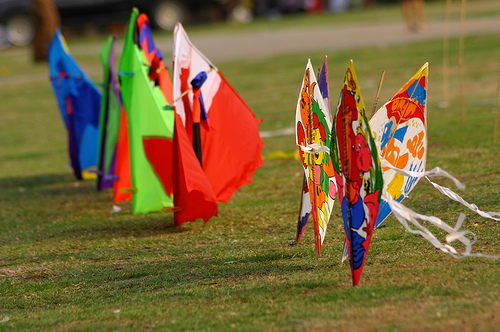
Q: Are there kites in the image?
A: Yes, there is a kite.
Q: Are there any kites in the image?
A: Yes, there is a kite.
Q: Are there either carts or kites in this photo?
A: Yes, there is a kite.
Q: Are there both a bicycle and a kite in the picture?
A: No, there is a kite but no bicycles.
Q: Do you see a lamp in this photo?
A: No, there are no lamps.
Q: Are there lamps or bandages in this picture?
A: No, there are no lamps or bandages.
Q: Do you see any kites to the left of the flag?
A: Yes, there is a kite to the left of the flag.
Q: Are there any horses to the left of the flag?
A: No, there is a kite to the left of the flag.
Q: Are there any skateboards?
A: No, there are no skateboards.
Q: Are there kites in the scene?
A: Yes, there is a kite.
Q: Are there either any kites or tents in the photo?
A: Yes, there is a kite.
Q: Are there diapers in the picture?
A: No, there are no diapers.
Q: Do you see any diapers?
A: No, there are no diapers.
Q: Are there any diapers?
A: No, there are no diapers.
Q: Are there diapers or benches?
A: No, there are no diapers or benches.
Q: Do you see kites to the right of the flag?
A: Yes, there is a kite to the right of the flag.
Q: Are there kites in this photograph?
A: Yes, there is a kite.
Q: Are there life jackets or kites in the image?
A: Yes, there is a kite.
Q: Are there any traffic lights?
A: No, there are no traffic lights.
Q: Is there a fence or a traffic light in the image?
A: No, there are no traffic lights or fences.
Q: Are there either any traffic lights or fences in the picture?
A: No, there are no traffic lights or fences.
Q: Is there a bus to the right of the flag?
A: No, there is a kite to the right of the flag.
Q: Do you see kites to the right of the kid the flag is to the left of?
A: Yes, there is a kite to the right of the child.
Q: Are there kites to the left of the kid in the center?
A: No, the kite is to the right of the child.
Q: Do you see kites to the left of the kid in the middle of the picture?
A: No, the kite is to the right of the child.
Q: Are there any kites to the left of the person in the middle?
A: No, the kite is to the right of the child.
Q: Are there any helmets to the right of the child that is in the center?
A: No, there is a kite to the right of the kid.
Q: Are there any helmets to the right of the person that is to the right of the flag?
A: No, there is a kite to the right of the kid.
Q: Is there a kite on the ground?
A: Yes, there is a kite on the ground.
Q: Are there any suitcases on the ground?
A: No, there is a kite on the ground.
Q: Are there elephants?
A: No, there are no elephants.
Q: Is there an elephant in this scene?
A: No, there are no elephants.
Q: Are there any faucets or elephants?
A: No, there are no elephants or faucets.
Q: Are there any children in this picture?
A: Yes, there is a child.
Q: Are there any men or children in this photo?
A: Yes, there is a child.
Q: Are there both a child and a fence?
A: No, there is a child but no fences.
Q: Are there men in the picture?
A: No, there are no men.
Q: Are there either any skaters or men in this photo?
A: No, there are no men or skaters.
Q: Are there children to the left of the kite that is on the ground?
A: Yes, there is a child to the left of the kite.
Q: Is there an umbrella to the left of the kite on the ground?
A: No, there is a child to the left of the kite.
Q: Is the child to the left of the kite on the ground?
A: Yes, the child is to the left of the kite.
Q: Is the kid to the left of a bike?
A: No, the kid is to the left of the kite.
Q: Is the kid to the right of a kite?
A: No, the kid is to the left of a kite.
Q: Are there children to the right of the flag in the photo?
A: Yes, there is a child to the right of the flag.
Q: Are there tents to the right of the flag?
A: No, there is a child to the right of the flag.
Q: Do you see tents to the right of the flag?
A: No, there is a child to the right of the flag.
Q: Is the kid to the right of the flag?
A: Yes, the kid is to the right of the flag.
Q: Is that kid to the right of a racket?
A: No, the kid is to the right of the flag.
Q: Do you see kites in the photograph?
A: Yes, there is a kite.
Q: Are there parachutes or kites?
A: Yes, there is a kite.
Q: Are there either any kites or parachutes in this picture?
A: Yes, there is a kite.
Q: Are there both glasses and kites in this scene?
A: No, there is a kite but no glasses.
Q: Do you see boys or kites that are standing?
A: Yes, the kite is standing.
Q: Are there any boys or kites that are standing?
A: Yes, the kite is standing.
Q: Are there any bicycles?
A: No, there are no bicycles.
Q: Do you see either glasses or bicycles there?
A: No, there are no bicycles or glasses.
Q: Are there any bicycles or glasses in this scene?
A: No, there are no bicycles or glasses.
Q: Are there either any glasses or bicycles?
A: No, there are no bicycles or glasses.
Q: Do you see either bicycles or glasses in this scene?
A: No, there are no bicycles or glasses.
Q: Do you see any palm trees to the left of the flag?
A: No, there is a kite to the left of the flag.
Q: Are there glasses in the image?
A: No, there are no glasses.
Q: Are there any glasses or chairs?
A: No, there are no glasses or chairs.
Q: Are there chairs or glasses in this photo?
A: No, there are no glasses or chairs.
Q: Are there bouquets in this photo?
A: No, there are no bouquets.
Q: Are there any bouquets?
A: No, there are no bouquets.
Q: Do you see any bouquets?
A: No, there are no bouquets.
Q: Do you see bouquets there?
A: No, there are no bouquets.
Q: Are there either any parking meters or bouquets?
A: No, there are no bouquets or parking meters.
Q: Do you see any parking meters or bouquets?
A: No, there are no bouquets or parking meters.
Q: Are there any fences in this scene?
A: No, there are no fences.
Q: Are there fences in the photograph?
A: No, there are no fences.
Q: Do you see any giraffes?
A: No, there are no giraffes.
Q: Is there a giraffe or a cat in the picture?
A: No, there are no giraffes or cats.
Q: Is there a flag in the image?
A: Yes, there is a flag.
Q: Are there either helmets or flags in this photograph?
A: Yes, there is a flag.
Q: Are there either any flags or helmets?
A: Yes, there is a flag.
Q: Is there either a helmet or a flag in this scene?
A: Yes, there is a flag.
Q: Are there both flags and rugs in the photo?
A: No, there is a flag but no rugs.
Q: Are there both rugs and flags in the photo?
A: No, there is a flag but no rugs.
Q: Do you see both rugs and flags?
A: No, there is a flag but no rugs.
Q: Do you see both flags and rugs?
A: No, there is a flag but no rugs.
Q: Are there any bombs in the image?
A: No, there are no bombs.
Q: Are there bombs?
A: No, there are no bombs.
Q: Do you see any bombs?
A: No, there are no bombs.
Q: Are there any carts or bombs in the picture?
A: No, there are no bombs or carts.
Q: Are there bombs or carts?
A: No, there are no bombs or carts.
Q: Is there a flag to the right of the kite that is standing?
A: Yes, there is a flag to the right of the kite.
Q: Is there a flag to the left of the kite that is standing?
A: No, the flag is to the right of the kite.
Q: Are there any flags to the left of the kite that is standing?
A: No, the flag is to the right of the kite.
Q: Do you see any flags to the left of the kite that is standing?
A: No, the flag is to the right of the kite.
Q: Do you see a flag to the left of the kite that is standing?
A: No, the flag is to the right of the kite.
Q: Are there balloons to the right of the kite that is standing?
A: No, there is a flag to the right of the kite.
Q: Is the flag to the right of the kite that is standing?
A: Yes, the flag is to the right of the kite.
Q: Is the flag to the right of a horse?
A: No, the flag is to the right of the kite.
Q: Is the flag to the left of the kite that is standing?
A: No, the flag is to the right of the kite.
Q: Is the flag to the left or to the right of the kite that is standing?
A: The flag is to the right of the kite.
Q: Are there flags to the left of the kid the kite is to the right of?
A: Yes, there is a flag to the left of the child.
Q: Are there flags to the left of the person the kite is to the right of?
A: Yes, there is a flag to the left of the child.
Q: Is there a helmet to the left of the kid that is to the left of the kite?
A: No, there is a flag to the left of the kid.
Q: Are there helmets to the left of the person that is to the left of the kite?
A: No, there is a flag to the left of the kid.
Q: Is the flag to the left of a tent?
A: No, the flag is to the left of the kid.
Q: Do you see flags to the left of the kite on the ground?
A: Yes, there is a flag to the left of the kite.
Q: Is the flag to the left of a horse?
A: No, the flag is to the left of the kite.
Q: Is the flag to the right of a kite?
A: No, the flag is to the left of a kite.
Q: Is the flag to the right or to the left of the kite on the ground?
A: The flag is to the left of the kite.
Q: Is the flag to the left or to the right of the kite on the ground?
A: The flag is to the left of the kite.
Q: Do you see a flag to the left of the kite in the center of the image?
A: Yes, there is a flag to the left of the kite.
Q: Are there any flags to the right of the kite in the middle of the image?
A: No, the flag is to the left of the kite.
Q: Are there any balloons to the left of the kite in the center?
A: No, there is a flag to the left of the kite.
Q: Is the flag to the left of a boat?
A: No, the flag is to the left of a kite.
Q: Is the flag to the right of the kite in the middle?
A: No, the flag is to the left of the kite.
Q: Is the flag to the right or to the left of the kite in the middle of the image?
A: The flag is to the left of the kite.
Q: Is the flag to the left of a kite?
A: Yes, the flag is to the left of a kite.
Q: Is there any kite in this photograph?
A: Yes, there is a kite.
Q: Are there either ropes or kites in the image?
A: Yes, there is a kite.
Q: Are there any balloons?
A: No, there are no balloons.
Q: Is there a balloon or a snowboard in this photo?
A: No, there are no balloons or snowboards.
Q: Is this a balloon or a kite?
A: This is a kite.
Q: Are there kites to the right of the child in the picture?
A: Yes, there is a kite to the right of the child.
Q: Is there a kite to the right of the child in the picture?
A: Yes, there is a kite to the right of the child.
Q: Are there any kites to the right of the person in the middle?
A: Yes, there is a kite to the right of the child.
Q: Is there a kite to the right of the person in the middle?
A: Yes, there is a kite to the right of the child.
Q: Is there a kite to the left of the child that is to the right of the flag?
A: No, the kite is to the right of the child.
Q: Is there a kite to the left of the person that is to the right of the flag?
A: No, the kite is to the right of the child.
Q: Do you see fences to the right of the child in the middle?
A: No, there is a kite to the right of the child.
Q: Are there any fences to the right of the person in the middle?
A: No, there is a kite to the right of the child.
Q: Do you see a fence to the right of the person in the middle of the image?
A: No, there is a kite to the right of the child.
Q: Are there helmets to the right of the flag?
A: No, there is a kite to the right of the flag.